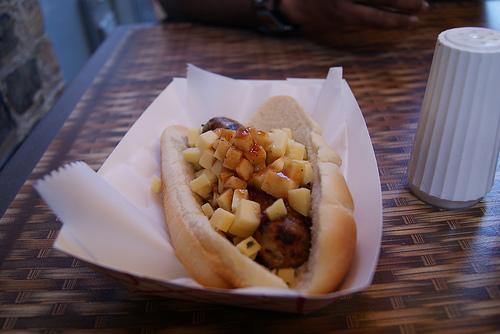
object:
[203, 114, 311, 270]
hot dog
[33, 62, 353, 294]
paper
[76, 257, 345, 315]
design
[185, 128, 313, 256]
topping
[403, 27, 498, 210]
salt shaker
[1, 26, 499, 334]
table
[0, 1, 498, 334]
restaurant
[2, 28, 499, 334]
pattern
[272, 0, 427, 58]
hand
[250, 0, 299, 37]
watch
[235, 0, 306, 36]
wrist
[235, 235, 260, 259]
cheese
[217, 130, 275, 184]
sauce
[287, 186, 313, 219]
cheese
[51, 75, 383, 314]
cardboard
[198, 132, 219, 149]
fruit piece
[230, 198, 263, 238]
fruit piece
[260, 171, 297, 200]
fruit piece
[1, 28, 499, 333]
mat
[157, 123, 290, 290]
left side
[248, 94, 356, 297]
right side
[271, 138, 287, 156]
chunks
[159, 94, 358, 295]
food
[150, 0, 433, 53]
person